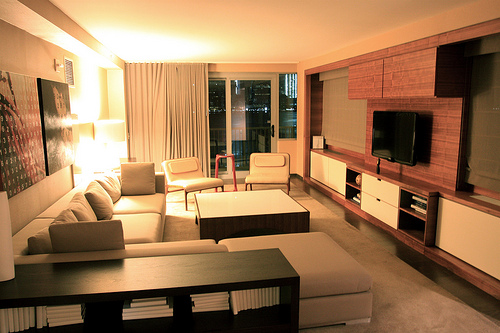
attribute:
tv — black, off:
[366, 109, 431, 168]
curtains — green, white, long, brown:
[125, 61, 212, 161]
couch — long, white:
[56, 162, 169, 251]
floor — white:
[83, 169, 463, 329]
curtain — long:
[117, 59, 215, 171]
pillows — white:
[96, 158, 155, 201]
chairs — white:
[163, 149, 296, 197]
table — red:
[208, 148, 242, 193]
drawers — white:
[359, 166, 401, 227]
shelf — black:
[1, 242, 302, 331]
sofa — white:
[54, 157, 174, 245]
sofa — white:
[1, 153, 181, 255]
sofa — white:
[29, 156, 183, 251]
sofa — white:
[40, 156, 180, 256]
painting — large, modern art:
[1, 65, 80, 187]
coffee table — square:
[190, 184, 316, 230]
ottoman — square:
[195, 186, 309, 232]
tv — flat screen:
[373, 109, 423, 164]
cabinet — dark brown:
[14, 245, 310, 331]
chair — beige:
[26, 166, 376, 318]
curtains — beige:
[119, 61, 209, 178]